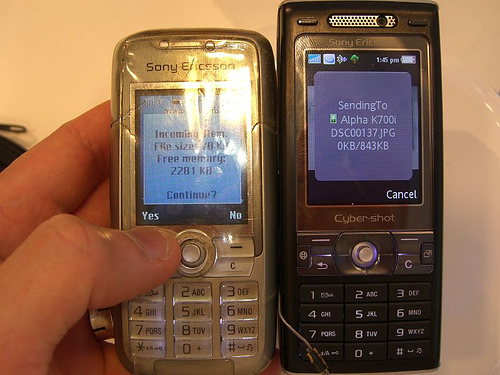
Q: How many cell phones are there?
A: Two.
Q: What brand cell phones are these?
A: Sony.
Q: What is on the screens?
A: Text messages.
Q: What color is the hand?
A: White.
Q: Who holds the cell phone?
A: A man.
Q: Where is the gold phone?
A: On the left.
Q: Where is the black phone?
A: On the right.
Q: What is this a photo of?
A: Two cell phones.